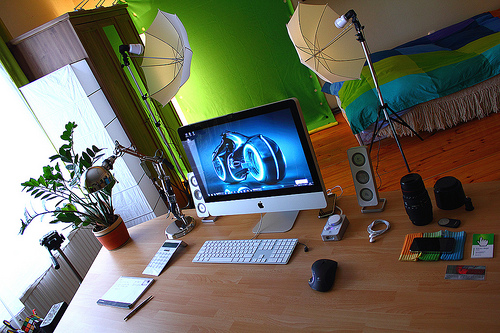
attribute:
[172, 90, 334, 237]
monitor — flat, apple, computer, mac, on, green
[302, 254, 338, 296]
mouse — black, wireless, cordless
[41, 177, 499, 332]
desk — brown, wooden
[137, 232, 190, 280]
calculator — small, solar, business, table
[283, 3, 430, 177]
lights — professional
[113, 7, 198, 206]
lights — professional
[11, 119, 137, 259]
houseplant — green, small, deocration, little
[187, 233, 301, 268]
keyboard — white, mac, cordless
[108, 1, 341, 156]
backdrop — green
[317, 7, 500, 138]
bedspread — geometric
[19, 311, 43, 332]
cube — rubrics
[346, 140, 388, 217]
sound system — surround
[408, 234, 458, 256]
iphone — charging, black, cell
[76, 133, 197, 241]
lamp — silver, desk, shiny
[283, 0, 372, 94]
umbrella — white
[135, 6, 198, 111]
umbrella — white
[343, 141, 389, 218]
speakers — computer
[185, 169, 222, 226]
speakers — computer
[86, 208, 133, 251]
pot — houseplant